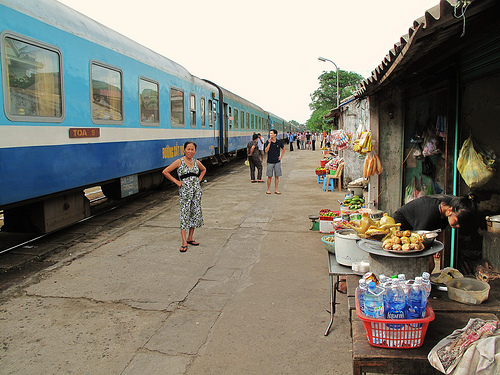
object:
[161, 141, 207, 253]
woman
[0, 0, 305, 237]
train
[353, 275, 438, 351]
basket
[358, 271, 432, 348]
water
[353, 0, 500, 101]
roof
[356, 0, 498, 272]
building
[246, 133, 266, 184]
people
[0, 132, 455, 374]
platform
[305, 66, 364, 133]
tree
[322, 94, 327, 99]
leaves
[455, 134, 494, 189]
bag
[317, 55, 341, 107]
light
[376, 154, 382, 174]
bananas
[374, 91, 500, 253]
wall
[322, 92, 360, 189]
building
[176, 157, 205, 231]
dress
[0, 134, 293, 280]
track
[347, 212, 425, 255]
food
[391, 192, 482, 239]
woman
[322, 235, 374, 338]
table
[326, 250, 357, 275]
edge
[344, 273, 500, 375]
table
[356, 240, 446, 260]
plate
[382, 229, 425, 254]
pastries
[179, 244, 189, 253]
flip flops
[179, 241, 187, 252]
feet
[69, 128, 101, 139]
sign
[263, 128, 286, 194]
man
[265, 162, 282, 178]
shorts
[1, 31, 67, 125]
window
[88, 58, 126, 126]
window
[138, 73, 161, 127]
window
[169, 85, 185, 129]
window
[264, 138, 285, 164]
shirt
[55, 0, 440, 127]
sky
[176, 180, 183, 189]
hands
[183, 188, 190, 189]
hips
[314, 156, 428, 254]
food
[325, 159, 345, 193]
chair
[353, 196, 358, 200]
bananas